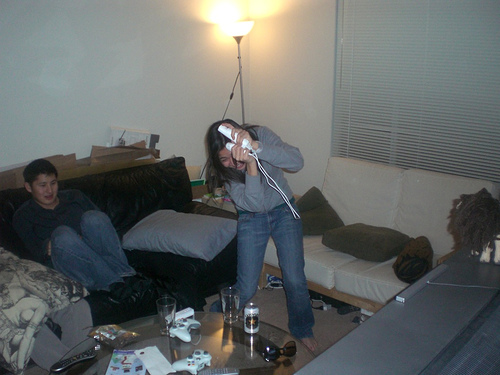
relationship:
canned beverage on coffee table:
[237, 300, 268, 334] [44, 308, 342, 372]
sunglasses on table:
[257, 337, 301, 364] [47, 307, 319, 374]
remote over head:
[216, 123, 252, 155] [199, 115, 265, 183]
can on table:
[243, 302, 259, 334] [47, 307, 319, 374]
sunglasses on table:
[257, 340, 297, 361] [47, 307, 319, 374]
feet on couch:
[103, 274, 160, 309] [0, 151, 249, 375]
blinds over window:
[331, 0, 498, 176] [338, 0, 498, 177]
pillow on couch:
[319, 220, 411, 263] [252, 158, 499, 309]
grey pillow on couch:
[122, 208, 237, 262] [4, 151, 249, 328]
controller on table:
[168, 347, 218, 374] [46, 305, 296, 373]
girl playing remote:
[198, 119, 318, 352] [216, 123, 252, 155]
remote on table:
[45, 344, 101, 375] [81, 360, 106, 373]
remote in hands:
[210, 120, 236, 144] [227, 133, 257, 169]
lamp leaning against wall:
[203, 19, 294, 114] [13, 15, 353, 121]